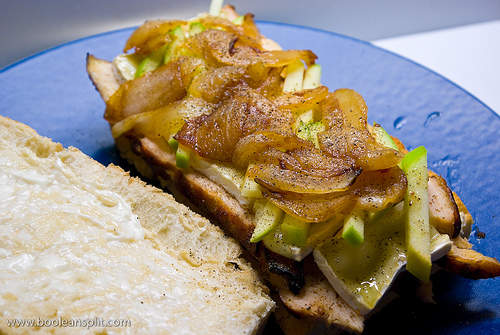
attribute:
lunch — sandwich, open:
[108, 68, 378, 267]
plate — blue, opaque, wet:
[409, 70, 477, 141]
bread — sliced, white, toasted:
[9, 130, 120, 325]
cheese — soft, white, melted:
[346, 261, 351, 277]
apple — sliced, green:
[416, 160, 432, 254]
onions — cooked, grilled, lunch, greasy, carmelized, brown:
[206, 59, 239, 92]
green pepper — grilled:
[137, 59, 166, 79]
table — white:
[460, 40, 489, 72]